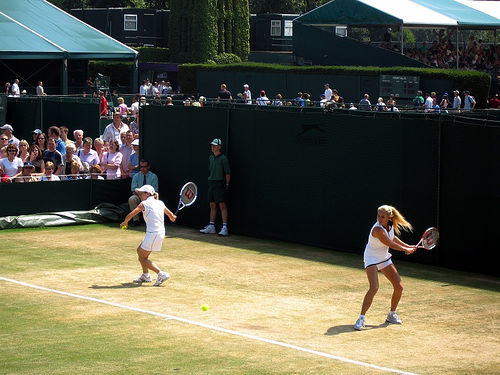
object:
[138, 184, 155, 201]
head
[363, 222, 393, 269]
cotton dress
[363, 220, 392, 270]
tennis dress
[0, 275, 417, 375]
line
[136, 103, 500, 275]
fence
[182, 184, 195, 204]
netting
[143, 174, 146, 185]
tie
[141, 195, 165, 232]
shirt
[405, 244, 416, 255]
both hands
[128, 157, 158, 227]
man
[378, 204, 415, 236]
hair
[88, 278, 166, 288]
shadow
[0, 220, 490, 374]
court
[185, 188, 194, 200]
red logo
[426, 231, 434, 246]
red logo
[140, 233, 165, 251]
shorts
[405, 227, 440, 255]
racket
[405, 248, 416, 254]
hand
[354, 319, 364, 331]
shoes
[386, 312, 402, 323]
shoes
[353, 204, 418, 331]
tennis player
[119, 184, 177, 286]
woman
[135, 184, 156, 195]
cap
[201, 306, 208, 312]
tennis ball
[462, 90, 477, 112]
person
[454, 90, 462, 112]
person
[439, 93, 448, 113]
person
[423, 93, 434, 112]
person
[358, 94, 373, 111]
person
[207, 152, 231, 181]
polo shirt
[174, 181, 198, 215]
racket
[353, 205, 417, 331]
girl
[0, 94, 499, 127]
stands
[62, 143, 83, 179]
spectator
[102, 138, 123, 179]
spectator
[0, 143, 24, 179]
spectator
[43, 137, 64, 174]
spectator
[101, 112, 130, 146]
spectator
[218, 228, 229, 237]
sneaker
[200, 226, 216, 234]
sneaker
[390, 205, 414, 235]
ponytail